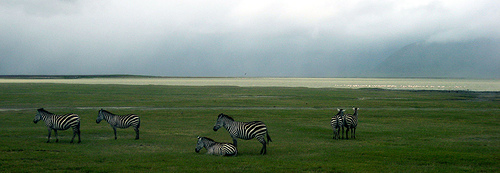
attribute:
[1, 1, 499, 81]
sky — blue, blue-gray, clear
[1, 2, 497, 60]
clouds — white, bright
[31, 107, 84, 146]
zebra — striped, walking, black, white, standing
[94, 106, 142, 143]
zebra — striped, black, white, standing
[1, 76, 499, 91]
water — shining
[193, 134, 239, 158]
zebra — black, white, laying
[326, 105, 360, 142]
zebras — side by side, standing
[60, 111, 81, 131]
stripes — black, white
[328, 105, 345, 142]
zebra — standing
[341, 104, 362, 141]
zebra — black, white, standing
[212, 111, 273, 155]
standing zebra — black, white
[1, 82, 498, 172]
grassy area — green